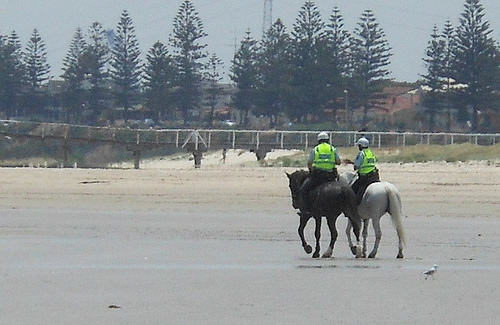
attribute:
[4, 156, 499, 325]
beach — sandy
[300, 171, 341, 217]
pants — black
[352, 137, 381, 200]
person — riding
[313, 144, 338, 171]
vest — reflective, green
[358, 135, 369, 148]
helmet — white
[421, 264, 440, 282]
bird — white, walking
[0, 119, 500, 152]
fence — white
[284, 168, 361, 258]
horse — black, walking, brown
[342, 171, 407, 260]
horse — white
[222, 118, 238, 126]
car — silver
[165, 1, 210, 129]
tree — tall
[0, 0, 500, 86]
sky — gray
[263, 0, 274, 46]
tower — tall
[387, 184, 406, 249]
tail — white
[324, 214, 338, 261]
leg — black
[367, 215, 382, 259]
leg — white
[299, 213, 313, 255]
leg — black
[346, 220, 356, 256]
leg — white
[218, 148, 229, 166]
woman — walking